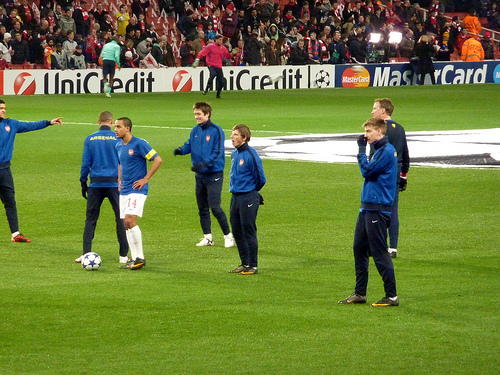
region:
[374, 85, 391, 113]
Person has brown hair.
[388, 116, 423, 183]
Person wearing blue shirt.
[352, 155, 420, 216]
Person wearing blue jacket.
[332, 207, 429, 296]
Person wearing blue pants.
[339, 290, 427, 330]
Person wearing black and yellow shoes.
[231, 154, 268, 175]
Person wearing blue jacket.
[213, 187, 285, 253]
Person wearing blue pants.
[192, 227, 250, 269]
Person wearing white tennis shoes.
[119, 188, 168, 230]
Person wearing white shorts.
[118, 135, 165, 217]
Person wearing blue shirt.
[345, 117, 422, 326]
soccar player wiping his nose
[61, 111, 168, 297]
soccar playing planning his next move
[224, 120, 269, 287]
a soccar player yawning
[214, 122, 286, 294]
soccar player yawning with his hands behind his back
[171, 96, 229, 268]
soccar playing laughing at teammate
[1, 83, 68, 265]
soccar player with red shoes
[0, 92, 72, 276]
soccar player giving instructions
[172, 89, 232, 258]
soccar player with short hair and white shoes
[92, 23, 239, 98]
two soccar players practicing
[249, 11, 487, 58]
crowd watching a soccar game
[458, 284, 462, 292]
part of a field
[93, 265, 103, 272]
part of a ball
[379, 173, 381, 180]
part of a jacket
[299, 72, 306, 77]
part of a board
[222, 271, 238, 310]
part of a lawn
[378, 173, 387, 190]
part of a jacket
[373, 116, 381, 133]
head of a man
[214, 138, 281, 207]
the jacket is blue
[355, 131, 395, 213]
the jacket is blue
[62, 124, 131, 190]
the jacket is blue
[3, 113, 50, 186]
the jacket is blue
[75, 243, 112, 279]
the ball is on the ground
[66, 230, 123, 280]
the ball is on the ground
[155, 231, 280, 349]
the field is green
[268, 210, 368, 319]
the field is green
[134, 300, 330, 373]
the field is green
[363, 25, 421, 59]
the lights are on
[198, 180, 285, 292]
the pants are black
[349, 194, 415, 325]
the pants are black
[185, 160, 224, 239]
the pants are black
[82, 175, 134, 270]
the pants are black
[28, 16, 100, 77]
people are standing up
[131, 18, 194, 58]
people are standing up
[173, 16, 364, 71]
people are standing up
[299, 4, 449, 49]
people are standing up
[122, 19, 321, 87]
people are standing up